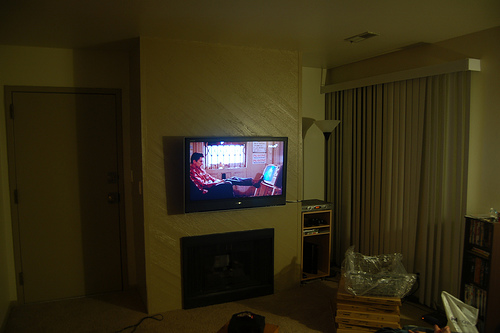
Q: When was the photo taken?
A: Nighttime.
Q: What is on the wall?
A: The television.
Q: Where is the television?
A: On the wall.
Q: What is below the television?
A: A fireplace.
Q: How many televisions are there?
A: One.